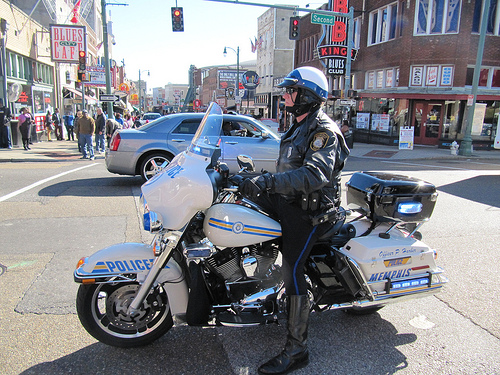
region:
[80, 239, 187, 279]
police written on the front tire cover.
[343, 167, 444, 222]
A black box on the back of bike.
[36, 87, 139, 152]
People on the sidewalk.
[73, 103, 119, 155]
People crossing the street.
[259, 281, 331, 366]
The police is wearing black boots.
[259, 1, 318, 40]
The traffic light is red.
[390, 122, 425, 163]
Posterboard in front of the store.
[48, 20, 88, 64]
square white sign with red lettering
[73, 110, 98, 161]
man in brown jacket and blue jeans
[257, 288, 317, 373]
black leather motorcycle boot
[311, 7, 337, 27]
green street sign with white lettering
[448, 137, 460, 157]
white fire hydrant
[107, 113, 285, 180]
bright silver four door sedan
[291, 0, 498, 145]
three story building of red brick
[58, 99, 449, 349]
white and blue police motorcycle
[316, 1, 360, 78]
black guitar shaped sign with red lettering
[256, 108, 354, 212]
black leather motorcycle jacket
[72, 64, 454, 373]
police officer on a motorcycle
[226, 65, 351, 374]
motorcycle cop wearing a jacket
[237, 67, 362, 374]
motorcycle cop wearing boots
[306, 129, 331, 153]
police department jacket patch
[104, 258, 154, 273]
light blue bold print reading Police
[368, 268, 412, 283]
blue print reading Memphis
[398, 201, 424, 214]
lit blue motorcycle light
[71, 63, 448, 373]
police officer on a white parked motorcycle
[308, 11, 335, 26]
green and white street sign reading Second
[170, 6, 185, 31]
traffic signal with a lit red light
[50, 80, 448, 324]
a police officer on a motorcycle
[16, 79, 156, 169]
people walking on the street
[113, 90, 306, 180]
a car on the street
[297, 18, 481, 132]
a building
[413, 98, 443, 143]
the door of the building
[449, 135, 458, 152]
a white fire hydrant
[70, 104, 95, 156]
a man waiting to cross the street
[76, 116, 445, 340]
a white motorcycle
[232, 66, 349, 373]
Cop riding a motorcycle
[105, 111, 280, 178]
Silver car passing a motorcycle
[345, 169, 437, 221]
Black box sitting on motorcycle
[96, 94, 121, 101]
Black and white traffic sign on pole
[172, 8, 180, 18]
Red traffic signal on traffic light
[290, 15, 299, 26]
Red traffic signal on traffic light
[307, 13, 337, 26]
Green and white street sign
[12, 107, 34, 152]
Woman wearing a pink shirt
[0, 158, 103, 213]
White line on street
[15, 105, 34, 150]
Woman wearing black apron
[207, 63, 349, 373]
a motorcycle cop on the beat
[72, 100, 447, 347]
a police motorcycle on the street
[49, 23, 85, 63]
a sign for the blues cafe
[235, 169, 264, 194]
a glove on the policeman's hand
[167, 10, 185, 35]
a traffic light above the street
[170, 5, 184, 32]
traffic light is red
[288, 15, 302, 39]
traffic light is red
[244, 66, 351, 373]
man is a police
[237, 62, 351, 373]
man is sitting on bike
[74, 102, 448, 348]
bike is in the middle of the street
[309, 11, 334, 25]
sign has street name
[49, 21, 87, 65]
sign is attached to building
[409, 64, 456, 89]
sign is above the door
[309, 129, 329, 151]
badge is on the jacket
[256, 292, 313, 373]
boot is on the foot